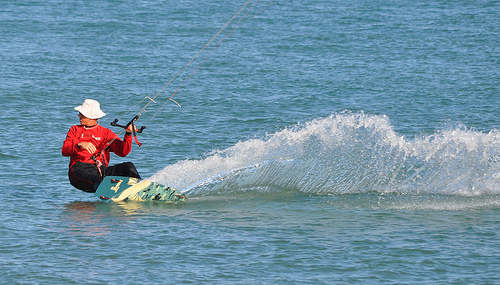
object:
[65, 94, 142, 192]
man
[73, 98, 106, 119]
hat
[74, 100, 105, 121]
white hat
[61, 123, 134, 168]
shirt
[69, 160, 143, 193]
pants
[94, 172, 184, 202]
surfboard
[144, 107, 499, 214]
wave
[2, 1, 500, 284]
water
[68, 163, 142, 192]
trousers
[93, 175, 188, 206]
board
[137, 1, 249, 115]
rope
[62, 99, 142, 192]
person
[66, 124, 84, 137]
shoulder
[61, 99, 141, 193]
surfer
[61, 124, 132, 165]
red shirt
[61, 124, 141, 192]
wetsuit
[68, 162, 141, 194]
black pants